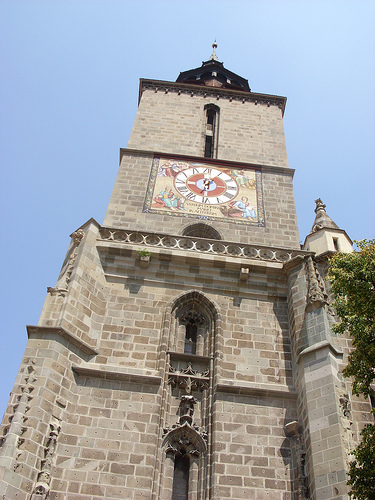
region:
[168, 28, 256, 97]
black and white church steeple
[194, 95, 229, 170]
tall slender church window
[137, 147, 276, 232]
church clock with mural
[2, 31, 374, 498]
large block church tower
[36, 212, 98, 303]
sculpture on a block tower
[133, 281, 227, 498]
designs on a church tower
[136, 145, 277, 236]
mural of saints on a tower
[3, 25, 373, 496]
large stone clock tower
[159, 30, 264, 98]
black church bell tower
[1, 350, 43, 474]
etchings on church tower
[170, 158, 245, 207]
Clock with roman numerals on face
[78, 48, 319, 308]
clock tower built of gray blocks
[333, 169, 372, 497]
tall leafy tree and bushes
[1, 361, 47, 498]
ornate brick work on corners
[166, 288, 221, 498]
two story archway entrance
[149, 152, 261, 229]
colorful figures painted around clock face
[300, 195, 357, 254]
stucco cupola atop side tower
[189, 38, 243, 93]
tall spire above bell tower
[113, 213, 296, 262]
third floor balcony with arched door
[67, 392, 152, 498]
brown and gray stone and brick work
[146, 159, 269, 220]
a large colorful clock.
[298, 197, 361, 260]
A tall tower near a clock tower.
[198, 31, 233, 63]
a lightning rod on a clock tower.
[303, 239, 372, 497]
a lush green leafy tree.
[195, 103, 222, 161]
an opening on the side of a building.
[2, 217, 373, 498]
the bottom half of a clock tower.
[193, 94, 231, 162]
an arch on a building.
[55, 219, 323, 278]
a ledge on a clock tower.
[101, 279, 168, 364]
a section of a brick clock tower.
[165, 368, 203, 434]
a sculpture on a tower.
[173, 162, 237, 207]
The clock on the tower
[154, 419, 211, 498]
The arch within and arch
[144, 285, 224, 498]
The long tall arch with another arch in it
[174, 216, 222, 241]
The small arch below the clock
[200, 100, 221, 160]
The thin arch over the clock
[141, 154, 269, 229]
The decorative square around the clock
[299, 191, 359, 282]
The smaller tower on the right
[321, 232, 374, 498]
The tree on the right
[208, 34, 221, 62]
The spire on top of the large tower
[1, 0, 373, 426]
The sky seen past the tower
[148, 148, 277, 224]
clock on the side of a tower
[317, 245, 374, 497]
green tree in front of the tower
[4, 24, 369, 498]
tall, light brown, brick tower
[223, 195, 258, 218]
painting of a woman in the corner of the clock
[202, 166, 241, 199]
roman numeral lining the clock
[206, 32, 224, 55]
pointy tip of the tower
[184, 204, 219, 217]
writing underneath the clock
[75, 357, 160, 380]
small ledge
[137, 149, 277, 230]
paintings of four people around the edge of the clock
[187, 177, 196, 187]
small white line